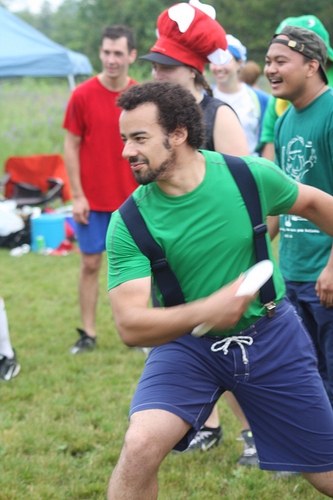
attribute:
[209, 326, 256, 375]
string — white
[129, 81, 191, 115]
hair — brown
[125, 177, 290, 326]
shirt — green, part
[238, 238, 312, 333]
frisbee — white, thrown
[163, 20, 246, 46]
hat — red, dark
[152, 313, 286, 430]
shorts — blue, part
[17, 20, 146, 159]
tent — blue, green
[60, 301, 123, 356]
sneaker — black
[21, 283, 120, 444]
field — part, grassy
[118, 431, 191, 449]
knee — part, edge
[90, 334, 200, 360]
elbow — part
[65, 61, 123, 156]
shirt — red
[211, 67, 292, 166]
shirt — white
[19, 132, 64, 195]
chair — orange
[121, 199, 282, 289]
suspenders — black, man's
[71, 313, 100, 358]
shoe — black